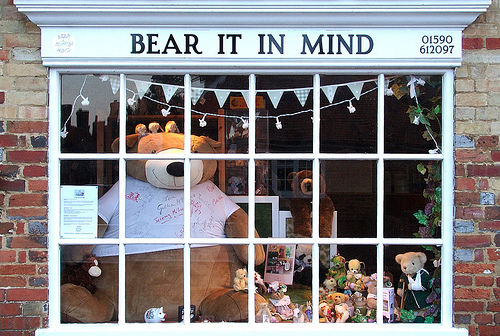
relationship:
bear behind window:
[279, 162, 348, 257] [64, 62, 446, 322]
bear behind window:
[390, 251, 436, 312] [64, 62, 446, 322]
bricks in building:
[2, 0, 495, 334] [0, 0, 498, 332]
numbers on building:
[414, 33, 460, 56] [0, 0, 498, 332]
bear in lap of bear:
[65, 121, 266, 324] [228, 262, 255, 295]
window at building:
[22, 2, 476, 334] [0, 0, 500, 336]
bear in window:
[65, 121, 266, 324] [22, 2, 476, 334]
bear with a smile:
[65, 121, 266, 324] [146, 163, 203, 189]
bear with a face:
[65, 121, 266, 324] [112, 119, 235, 193]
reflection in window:
[60, 71, 172, 152] [64, 62, 446, 322]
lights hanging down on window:
[56, 75, 446, 187] [22, 2, 476, 334]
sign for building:
[39, 28, 460, 60] [0, 0, 500, 336]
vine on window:
[396, 76, 441, 322] [64, 62, 446, 322]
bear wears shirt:
[65, 121, 266, 324] [89, 174, 242, 261]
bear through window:
[65, 121, 266, 324] [64, 62, 446, 322]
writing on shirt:
[122, 181, 223, 228] [92, 169, 237, 254]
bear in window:
[49, 111, 279, 324] [22, 2, 476, 334]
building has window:
[0, 0, 500, 336] [64, 62, 446, 322]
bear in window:
[65, 121, 266, 324] [45, 52, 463, 304]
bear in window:
[395, 251, 435, 323] [45, 52, 463, 304]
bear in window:
[321, 292, 349, 323] [45, 52, 463, 304]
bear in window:
[233, 268, 248, 291] [45, 52, 463, 304]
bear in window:
[287, 170, 336, 238] [45, 52, 463, 304]